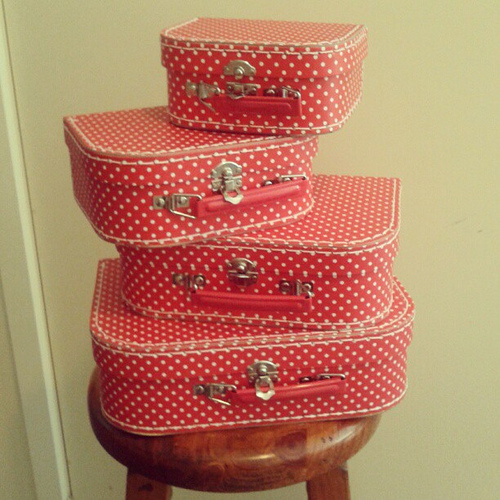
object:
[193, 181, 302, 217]
handle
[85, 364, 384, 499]
stool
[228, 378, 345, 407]
handle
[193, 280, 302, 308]
handle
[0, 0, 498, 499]
wall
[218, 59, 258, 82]
latch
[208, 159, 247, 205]
latch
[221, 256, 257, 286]
latch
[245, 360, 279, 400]
latch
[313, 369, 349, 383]
latch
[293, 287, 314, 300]
latch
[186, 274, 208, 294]
latch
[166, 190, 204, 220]
latch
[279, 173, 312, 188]
latch